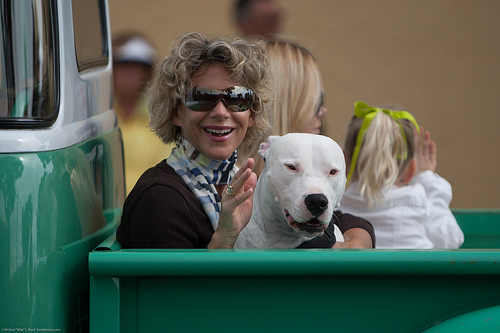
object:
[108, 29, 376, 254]
people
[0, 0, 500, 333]
truck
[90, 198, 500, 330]
rear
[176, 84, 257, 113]
sunglasses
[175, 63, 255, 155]
face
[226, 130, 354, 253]
dog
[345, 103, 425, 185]
ribbons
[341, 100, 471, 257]
girl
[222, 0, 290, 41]
man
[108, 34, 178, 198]
man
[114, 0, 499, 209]
background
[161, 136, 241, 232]
scarf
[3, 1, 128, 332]
cab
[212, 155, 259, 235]
hand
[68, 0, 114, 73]
back window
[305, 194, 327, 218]
nose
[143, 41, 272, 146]
hair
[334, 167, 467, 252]
coat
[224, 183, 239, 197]
ring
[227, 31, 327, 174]
woman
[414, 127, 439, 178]
hand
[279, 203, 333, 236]
mouth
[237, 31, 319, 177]
blonde hair